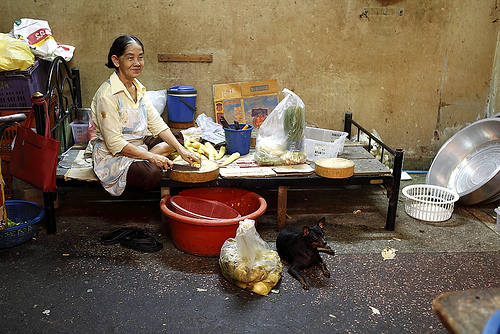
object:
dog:
[274, 211, 341, 291]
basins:
[154, 179, 271, 261]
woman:
[83, 32, 205, 198]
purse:
[7, 99, 60, 191]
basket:
[401, 180, 462, 224]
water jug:
[167, 85, 197, 123]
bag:
[251, 86, 311, 168]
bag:
[12, 14, 77, 64]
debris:
[376, 243, 406, 261]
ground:
[3, 185, 500, 333]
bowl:
[427, 118, 500, 207]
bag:
[212, 212, 288, 299]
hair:
[102, 32, 150, 71]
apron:
[88, 77, 156, 199]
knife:
[165, 159, 199, 175]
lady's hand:
[143, 148, 174, 176]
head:
[109, 32, 150, 79]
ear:
[108, 52, 122, 70]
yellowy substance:
[222, 259, 283, 298]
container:
[1, 197, 47, 245]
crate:
[66, 113, 90, 148]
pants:
[125, 141, 173, 194]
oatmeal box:
[207, 77, 286, 142]